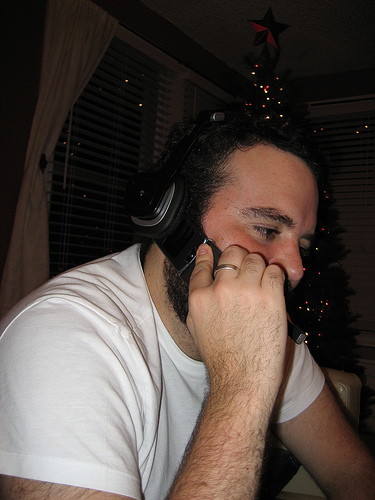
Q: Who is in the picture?
A: A man.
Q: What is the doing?
A: Talking on the phone.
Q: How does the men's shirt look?
A: White.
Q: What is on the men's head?
A: Headphones.